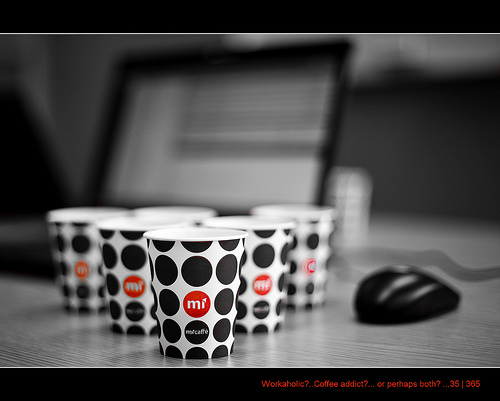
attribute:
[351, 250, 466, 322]
mouse — pc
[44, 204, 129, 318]
cup — polka dots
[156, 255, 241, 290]
dots — black, three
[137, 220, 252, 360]
cup — paper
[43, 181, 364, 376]
cups — paper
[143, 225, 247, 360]
cup — white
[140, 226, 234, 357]
cup — black, red, white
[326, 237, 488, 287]
cord — black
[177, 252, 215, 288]
polka dot — black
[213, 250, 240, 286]
polka dot — black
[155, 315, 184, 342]
polka dot — black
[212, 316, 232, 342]
polka dot — black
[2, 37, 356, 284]
laptop — open, black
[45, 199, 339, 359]
cups — polka dots, drinking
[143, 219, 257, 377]
cup — polka dot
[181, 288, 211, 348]
coffee — name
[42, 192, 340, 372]
pattern — pyramid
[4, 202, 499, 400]
desk — wood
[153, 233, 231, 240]
interior — white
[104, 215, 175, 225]
interior — white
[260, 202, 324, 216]
interior — white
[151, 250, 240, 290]
dots — black